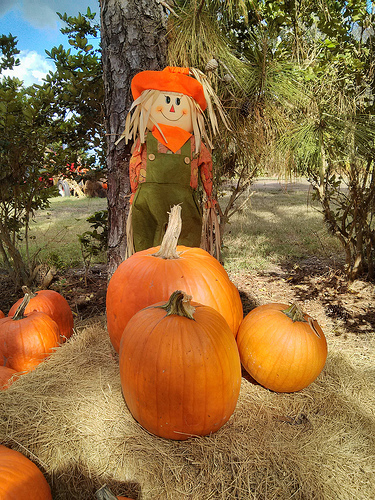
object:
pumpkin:
[101, 205, 243, 368]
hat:
[130, 63, 207, 111]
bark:
[106, 110, 120, 148]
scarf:
[150, 125, 191, 153]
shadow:
[221, 182, 359, 270]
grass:
[0, 301, 375, 499]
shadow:
[44, 459, 143, 499]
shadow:
[122, 360, 375, 500]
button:
[181, 156, 191, 166]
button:
[147, 153, 155, 163]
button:
[141, 169, 147, 178]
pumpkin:
[117, 293, 241, 439]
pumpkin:
[234, 298, 329, 396]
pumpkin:
[0, 291, 61, 372]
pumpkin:
[0, 445, 50, 498]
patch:
[44, 210, 81, 266]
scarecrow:
[113, 66, 223, 283]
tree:
[95, 1, 212, 290]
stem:
[156, 202, 183, 259]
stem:
[158, 289, 199, 321]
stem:
[12, 291, 30, 318]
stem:
[285, 302, 303, 322]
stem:
[19, 284, 36, 298]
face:
[146, 89, 194, 133]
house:
[35, 160, 106, 201]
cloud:
[0, 49, 55, 94]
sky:
[1, 0, 372, 173]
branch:
[302, 140, 341, 236]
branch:
[77, 37, 86, 44]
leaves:
[333, 178, 341, 187]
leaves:
[87, 8, 93, 20]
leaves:
[54, 11, 64, 20]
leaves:
[44, 48, 54, 57]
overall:
[130, 128, 202, 259]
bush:
[0, 32, 64, 289]